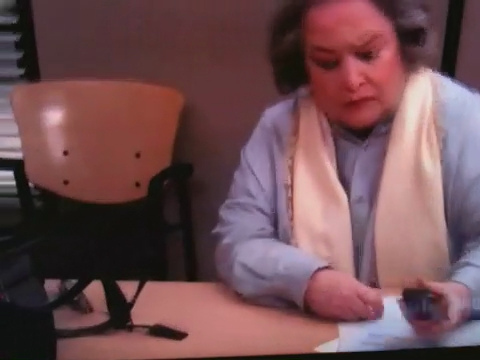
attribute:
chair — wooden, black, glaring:
[6, 78, 197, 281]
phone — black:
[402, 286, 448, 322]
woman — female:
[210, 1, 480, 337]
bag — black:
[1, 247, 58, 360]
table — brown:
[44, 279, 338, 360]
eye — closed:
[315, 53, 339, 69]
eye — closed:
[356, 49, 382, 61]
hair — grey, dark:
[372, 1, 429, 48]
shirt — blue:
[211, 70, 480, 317]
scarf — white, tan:
[286, 93, 351, 274]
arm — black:
[147, 162, 193, 186]